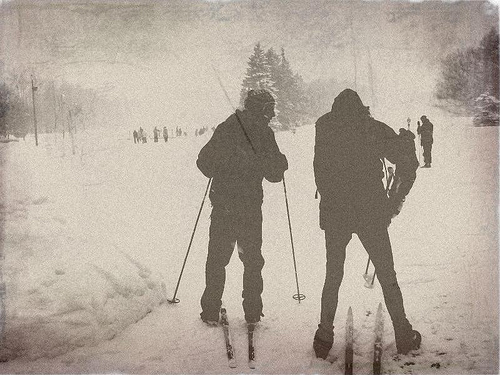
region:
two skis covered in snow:
[343, 299, 388, 373]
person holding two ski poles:
[172, 71, 309, 363]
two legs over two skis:
[197, 226, 269, 368]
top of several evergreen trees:
[226, 33, 304, 85]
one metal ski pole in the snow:
[280, 185, 310, 310]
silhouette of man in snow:
[297, 80, 421, 366]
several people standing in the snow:
[103, 113, 205, 150]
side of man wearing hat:
[228, 79, 281, 126]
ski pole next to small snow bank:
[11, 179, 202, 367]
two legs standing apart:
[311, 211, 428, 363]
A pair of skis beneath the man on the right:
[343, 297, 395, 374]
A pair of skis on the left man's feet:
[199, 298, 264, 366]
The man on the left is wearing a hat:
[248, 86, 275, 113]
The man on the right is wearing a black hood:
[327, 85, 376, 125]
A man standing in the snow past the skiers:
[414, 112, 442, 170]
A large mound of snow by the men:
[9, 203, 129, 325]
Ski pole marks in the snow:
[125, 264, 168, 301]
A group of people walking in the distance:
[130, 119, 212, 149]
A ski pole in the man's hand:
[272, 151, 314, 304]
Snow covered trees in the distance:
[242, 50, 300, 138]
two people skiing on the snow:
[3, 8, 494, 371]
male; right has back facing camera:
[308, 85, 420, 362]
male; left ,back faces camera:
[200, 87, 288, 331]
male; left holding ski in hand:
[277, 173, 306, 308]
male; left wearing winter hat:
[242, 85, 279, 122]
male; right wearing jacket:
[314, 85, 391, 232]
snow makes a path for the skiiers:
[0, 235, 160, 362]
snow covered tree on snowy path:
[429, 59, 499, 134]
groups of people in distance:
[127, 118, 195, 143]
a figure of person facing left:
[412, 110, 442, 167]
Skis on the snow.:
[339, 300, 389, 373]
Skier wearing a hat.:
[235, 83, 278, 126]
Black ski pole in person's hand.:
[272, 165, 305, 314]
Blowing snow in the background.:
[8, 6, 498, 156]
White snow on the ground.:
[118, 151, 498, 270]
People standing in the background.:
[129, 116, 214, 146]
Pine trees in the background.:
[236, 40, 309, 135]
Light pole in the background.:
[26, 73, 41, 146]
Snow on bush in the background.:
[470, 90, 498, 127]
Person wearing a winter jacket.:
[306, 86, 420, 367]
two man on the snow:
[154, 73, 439, 365]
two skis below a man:
[333, 281, 390, 372]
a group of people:
[129, 108, 209, 150]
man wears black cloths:
[294, 80, 429, 365]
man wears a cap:
[217, 74, 288, 151]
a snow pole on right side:
[269, 151, 316, 313]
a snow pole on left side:
[156, 170, 219, 316]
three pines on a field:
[219, 38, 357, 134]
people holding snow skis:
[396, 108, 441, 168]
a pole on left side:
[23, 71, 53, 153]